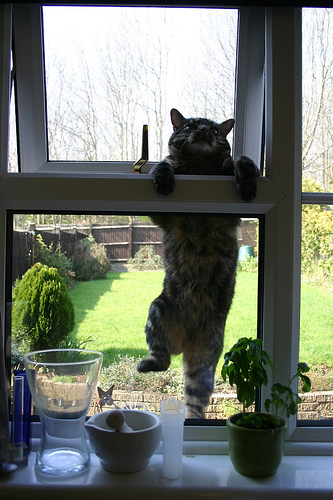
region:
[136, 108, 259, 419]
a cat climbing in a window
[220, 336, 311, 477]
small potted plant on a windowsil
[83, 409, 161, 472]
mortar and pestle on the windowsil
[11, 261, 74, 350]
a large green bush outside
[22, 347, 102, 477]
a glass vase on the windowsil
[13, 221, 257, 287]
a wooden fence in the back yard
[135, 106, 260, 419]
cat is climbing a window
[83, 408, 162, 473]
mortel and pestal is white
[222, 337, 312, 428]
plant is small and green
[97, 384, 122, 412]
dog is watching the cat climb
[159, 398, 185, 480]
container is made of plastic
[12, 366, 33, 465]
blue vase is long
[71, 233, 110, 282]
shrub is in the shade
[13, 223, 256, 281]
fence is made of wood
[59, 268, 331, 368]
lawn is green and trimmed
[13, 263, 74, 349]
bush is green and trimmed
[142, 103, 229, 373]
cat climbing on window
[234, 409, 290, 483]
green pot on window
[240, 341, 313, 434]
green plant in pot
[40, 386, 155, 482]
white mortar and pestle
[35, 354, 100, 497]
hourglass shaped vase on window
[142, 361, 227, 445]
cat has grey legs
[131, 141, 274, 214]
cat has dark grey paws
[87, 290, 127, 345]
green grass outside window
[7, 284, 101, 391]
green bush outside window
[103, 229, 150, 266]
brown fence in distance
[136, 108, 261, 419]
gray cat hanging from window.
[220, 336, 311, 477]
A plant in green pot.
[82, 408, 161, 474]
A white pestle and mortar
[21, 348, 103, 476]
A clear glass vase.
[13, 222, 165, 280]
A wooden fence in the distance.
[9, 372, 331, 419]
A brick wall in distance.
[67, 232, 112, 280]
A bush in the distance.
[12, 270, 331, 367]
A green grass lawn.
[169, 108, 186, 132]
Ear of gray cat.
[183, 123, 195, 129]
Eye of cat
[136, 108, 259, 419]
cat climbing in a window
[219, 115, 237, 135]
a cat's left ear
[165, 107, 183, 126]
a cat's right ear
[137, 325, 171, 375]
a cat's right foot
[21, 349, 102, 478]
small clear glass vase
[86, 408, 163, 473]
ceramic mortar and pestle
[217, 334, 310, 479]
green house plant in container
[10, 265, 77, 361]
short green shrub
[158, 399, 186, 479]
small plastic tube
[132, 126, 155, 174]
shiny brass window latch